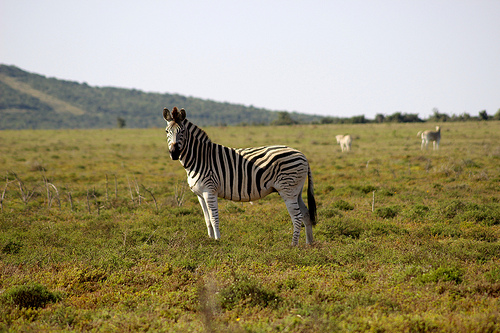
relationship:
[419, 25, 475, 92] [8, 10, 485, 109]
clouds in sky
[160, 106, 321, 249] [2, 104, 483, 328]
zebra standing in foreground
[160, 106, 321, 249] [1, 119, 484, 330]
zebra standing in field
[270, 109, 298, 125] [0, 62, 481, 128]
tree standing in background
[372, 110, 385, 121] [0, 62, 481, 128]
tree standing in background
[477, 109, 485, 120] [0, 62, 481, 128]
tree standing in background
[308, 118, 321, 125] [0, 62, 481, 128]
tree standing in background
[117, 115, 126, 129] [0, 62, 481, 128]
tree standing in background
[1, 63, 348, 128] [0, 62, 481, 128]
hill standing in background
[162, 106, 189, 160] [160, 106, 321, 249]
head belonging to zebra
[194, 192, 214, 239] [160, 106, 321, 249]
front leg belonging to zebra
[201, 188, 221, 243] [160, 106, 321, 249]
front leg belonging to zebra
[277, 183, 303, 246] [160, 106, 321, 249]
back leg belonging to zebra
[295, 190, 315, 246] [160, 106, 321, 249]
back leg belonging to zebra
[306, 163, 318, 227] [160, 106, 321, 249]
tail belonging to zebra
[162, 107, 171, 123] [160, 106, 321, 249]
ear belonging to zebra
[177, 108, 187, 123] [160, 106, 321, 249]
ear belonging to zebra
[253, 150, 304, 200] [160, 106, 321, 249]
stripe adorning zebra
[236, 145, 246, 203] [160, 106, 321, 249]
stripe adorning zebra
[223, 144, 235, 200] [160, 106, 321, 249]
stripe adorning zebra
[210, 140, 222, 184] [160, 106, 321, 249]
stripe adorning zebra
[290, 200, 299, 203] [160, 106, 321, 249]
stripe adorning zebra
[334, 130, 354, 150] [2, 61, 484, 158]
animal standing in background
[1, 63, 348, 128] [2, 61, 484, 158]
hill standing in background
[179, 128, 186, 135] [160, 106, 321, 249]
eye belonging to zebra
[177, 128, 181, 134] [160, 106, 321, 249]
eye belonging to zebra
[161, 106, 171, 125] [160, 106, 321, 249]
ear belonging to zebra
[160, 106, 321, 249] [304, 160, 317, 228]
zebra swinging tail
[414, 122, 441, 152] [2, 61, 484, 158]
llama standing in background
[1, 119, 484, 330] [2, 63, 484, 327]
field growing in wilderness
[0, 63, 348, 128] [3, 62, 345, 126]
hill with trees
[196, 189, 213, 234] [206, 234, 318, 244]
front leg with hooves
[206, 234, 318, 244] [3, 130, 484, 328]
hooves hidden by grass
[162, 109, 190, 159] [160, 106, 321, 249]
head of zebra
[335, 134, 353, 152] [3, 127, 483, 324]
animal grazing in pasture